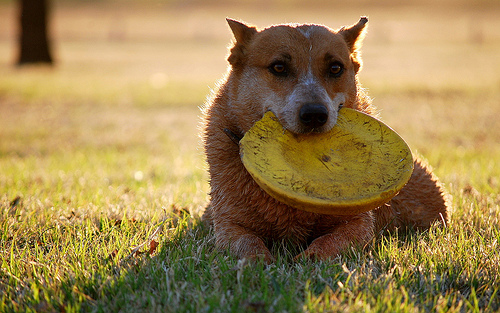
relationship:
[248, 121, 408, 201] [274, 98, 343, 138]
frisbee in dog's mouth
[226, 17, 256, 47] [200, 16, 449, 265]
ear of dog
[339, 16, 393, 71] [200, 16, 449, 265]
ear of dog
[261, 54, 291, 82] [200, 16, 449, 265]
eye of dog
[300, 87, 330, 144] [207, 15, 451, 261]
nose of brown dog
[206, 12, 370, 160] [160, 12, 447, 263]
head of dog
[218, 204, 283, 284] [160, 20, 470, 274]
leg of dog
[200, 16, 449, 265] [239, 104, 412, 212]
dog chewing frisbee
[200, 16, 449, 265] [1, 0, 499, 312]
dog laying in grass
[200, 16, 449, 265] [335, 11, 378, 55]
dog has ear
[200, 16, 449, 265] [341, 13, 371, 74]
dog has ear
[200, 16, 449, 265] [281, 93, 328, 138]
dog has nose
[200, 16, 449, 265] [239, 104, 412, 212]
dog has frisbee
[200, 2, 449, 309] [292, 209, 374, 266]
dog has leg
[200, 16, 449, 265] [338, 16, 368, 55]
dog has ear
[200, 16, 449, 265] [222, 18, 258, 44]
dog has ear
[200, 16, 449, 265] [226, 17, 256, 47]
dog has ear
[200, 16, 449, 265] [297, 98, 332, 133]
dog has nose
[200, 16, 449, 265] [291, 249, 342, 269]
dog has paws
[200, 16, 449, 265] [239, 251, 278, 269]
dog has paws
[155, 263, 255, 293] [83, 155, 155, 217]
shadow on grass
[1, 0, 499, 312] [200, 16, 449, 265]
grass near dog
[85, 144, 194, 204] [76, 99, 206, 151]
green grass with brown grass